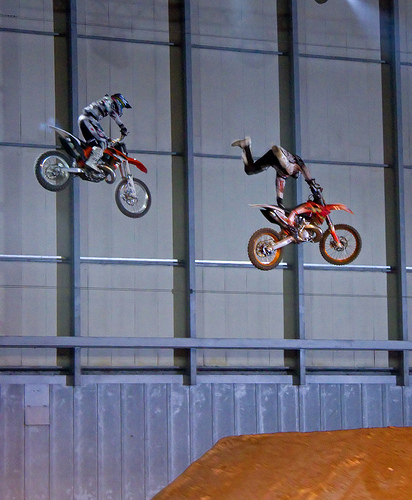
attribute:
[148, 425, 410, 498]
track — upward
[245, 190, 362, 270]
dirt bike — red and orange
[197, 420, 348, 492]
mound — sand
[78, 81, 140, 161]
dirt bike — in the air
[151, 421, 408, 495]
ramp — brown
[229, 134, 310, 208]
rider — first 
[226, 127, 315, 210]
rider — second 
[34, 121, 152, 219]
dirt bike — in the air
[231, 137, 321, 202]
person — perfoming 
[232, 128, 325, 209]
rider — doing a trick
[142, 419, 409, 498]
mound — sand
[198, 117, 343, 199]
person — doing tricks 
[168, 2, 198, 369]
rod — iron 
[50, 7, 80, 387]
rod — iron 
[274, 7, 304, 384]
rod — iron 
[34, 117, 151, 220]
bike — red and black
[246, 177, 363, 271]
bike — second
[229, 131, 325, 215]
rider — standing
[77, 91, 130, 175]
person — standing 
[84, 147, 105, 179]
boots — white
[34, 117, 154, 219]
motorcycle — jumping 